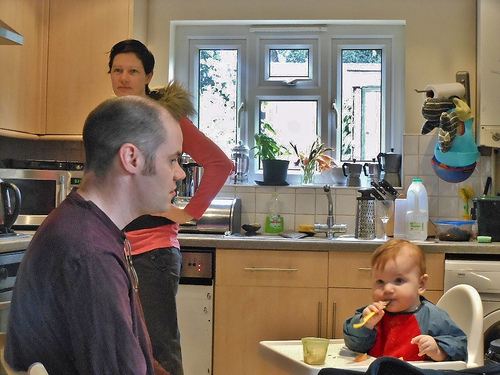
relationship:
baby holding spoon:
[341, 234, 467, 363] [347, 297, 394, 331]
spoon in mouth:
[347, 297, 394, 331] [379, 296, 401, 306]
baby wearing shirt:
[341, 234, 467, 363] [343, 299, 471, 361]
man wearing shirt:
[5, 96, 190, 374] [6, 183, 155, 373]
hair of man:
[80, 99, 167, 179] [5, 96, 190, 374]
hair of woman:
[102, 37, 157, 73] [105, 37, 237, 374]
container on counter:
[403, 176, 432, 243] [182, 240, 498, 253]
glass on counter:
[376, 199, 392, 243] [182, 240, 498, 253]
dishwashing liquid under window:
[264, 188, 286, 235] [169, 19, 401, 186]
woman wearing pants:
[105, 37, 237, 374] [132, 248, 186, 372]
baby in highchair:
[341, 234, 467, 363] [256, 283, 489, 373]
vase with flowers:
[298, 165, 318, 182] [290, 136, 338, 176]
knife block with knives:
[382, 192, 436, 241] [365, 177, 399, 204]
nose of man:
[174, 161, 188, 181] [5, 96, 190, 374]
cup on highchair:
[296, 332, 332, 371] [256, 283, 489, 373]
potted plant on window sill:
[252, 122, 290, 187] [190, 179, 405, 190]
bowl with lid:
[428, 214, 477, 243] [431, 218, 478, 227]